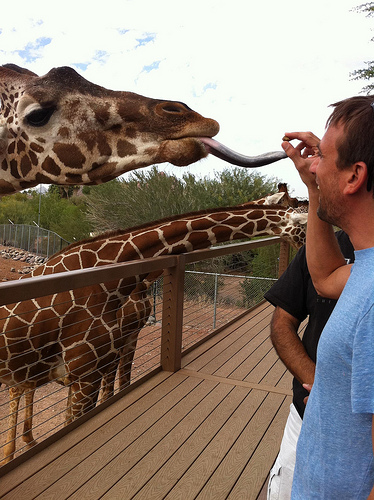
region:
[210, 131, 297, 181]
Giraffe has long tongue sticking out.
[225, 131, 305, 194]
End of giraffe's tongue is black.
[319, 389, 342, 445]
Person wearing blue shirt.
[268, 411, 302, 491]
Person wearing khaki pants.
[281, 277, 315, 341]
Person wearing black shirt.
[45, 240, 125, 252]
Giraffe has brown hair down neck.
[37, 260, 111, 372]
Giraffe is brown and tan.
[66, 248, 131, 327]
Giraffe is standing behind fence.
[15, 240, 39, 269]
Large gray rocks near fence.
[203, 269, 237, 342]
Gray chain link fence to the right of giraffe.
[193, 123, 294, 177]
Tongue of a giraffe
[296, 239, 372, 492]
A blue t-shirt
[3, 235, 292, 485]
A fence in front of the giraffe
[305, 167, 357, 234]
Facial hair on man's face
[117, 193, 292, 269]
Long neck of a giraffe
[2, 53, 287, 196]
Giraffe sticking out its tongue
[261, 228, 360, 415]
A black shirt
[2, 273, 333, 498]
A brown wooden deck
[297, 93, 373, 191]
Man has brown hair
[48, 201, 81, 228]
Green leaves on a tree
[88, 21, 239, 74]
White clouds in the sky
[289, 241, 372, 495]
A blue shirt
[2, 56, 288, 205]
A giraffe sticking its tongue out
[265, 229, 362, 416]
A black t-shirt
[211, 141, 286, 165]
the tongue of a giraffe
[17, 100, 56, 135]
an eye of a giraffe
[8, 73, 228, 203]
the head of a giraffe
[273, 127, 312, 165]
the fingers of a hand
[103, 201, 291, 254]
a neck of a giraffe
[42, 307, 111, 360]
the spots on a giraffe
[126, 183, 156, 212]
the leaves of a tree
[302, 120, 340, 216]
the face of a person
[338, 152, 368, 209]
an ear of a person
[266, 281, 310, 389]
the arm of a person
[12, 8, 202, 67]
Blue sky and white clouds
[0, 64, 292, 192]
Giraffe reaching his tounge out to eat food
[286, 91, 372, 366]
Guy feeding a giraffe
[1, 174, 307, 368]
Giraffe behind a fence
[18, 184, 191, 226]
Green, leafy, tall, trees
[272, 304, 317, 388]
White guy's hair arm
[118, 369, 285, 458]
Brown stained, wooden deck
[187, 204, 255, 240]
Brown and white spots on Giraffe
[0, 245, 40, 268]
A lot of different rocks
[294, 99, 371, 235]
Guy smiling at a giraffe